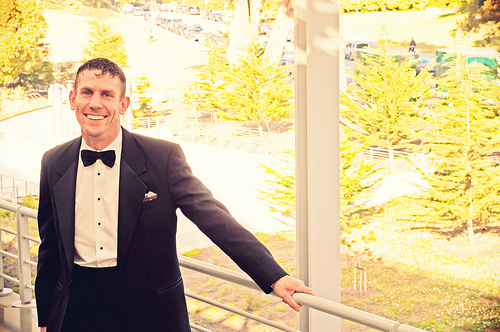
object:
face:
[68, 80, 130, 138]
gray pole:
[294, 0, 341, 332]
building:
[0, 0, 432, 332]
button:
[98, 222, 102, 225]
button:
[100, 247, 104, 250]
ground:
[403, 149, 428, 194]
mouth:
[78, 110, 115, 124]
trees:
[410, 187, 500, 237]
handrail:
[176, 253, 430, 332]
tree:
[436, 0, 494, 48]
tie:
[81, 149, 116, 168]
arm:
[191, 196, 280, 279]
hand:
[270, 275, 320, 312]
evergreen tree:
[395, 156, 500, 242]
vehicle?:
[187, 5, 199, 15]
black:
[81, 149, 116, 168]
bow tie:
[81, 149, 116, 168]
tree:
[191, 57, 269, 105]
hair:
[73, 57, 127, 102]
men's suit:
[35, 125, 290, 332]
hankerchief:
[143, 191, 158, 203]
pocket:
[141, 190, 162, 211]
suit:
[34, 125, 289, 332]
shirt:
[73, 126, 122, 269]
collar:
[56, 125, 148, 177]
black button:
[97, 173, 100, 176]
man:
[35, 57, 317, 332]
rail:
[212, 254, 431, 332]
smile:
[73, 85, 121, 130]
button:
[98, 197, 101, 200]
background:
[347, 149, 477, 291]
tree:
[0, 0, 51, 86]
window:
[0, 0, 500, 332]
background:
[3, 0, 500, 90]